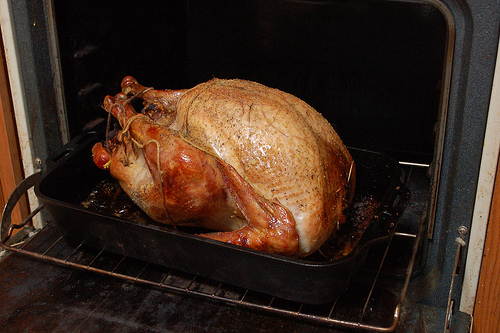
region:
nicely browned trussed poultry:
[79, 68, 364, 273]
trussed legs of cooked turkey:
[97, 67, 174, 137]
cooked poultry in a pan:
[33, 63, 422, 292]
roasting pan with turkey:
[28, 53, 418, 308]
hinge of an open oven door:
[4, 147, 60, 244]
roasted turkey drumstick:
[98, 86, 230, 217]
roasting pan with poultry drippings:
[326, 131, 413, 270]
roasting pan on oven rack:
[12, 48, 424, 329]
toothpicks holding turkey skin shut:
[320, 149, 368, 236]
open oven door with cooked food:
[5, 8, 489, 331]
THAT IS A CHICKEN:
[100, 72, 346, 249]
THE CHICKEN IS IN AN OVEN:
[101, 71, 356, 241]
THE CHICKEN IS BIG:
[95, 76, 351, 243]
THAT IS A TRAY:
[340, 191, 372, 257]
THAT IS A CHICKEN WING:
[211, 147, 295, 262]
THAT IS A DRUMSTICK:
[106, 90, 222, 200]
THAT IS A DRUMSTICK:
[126, 79, 183, 107]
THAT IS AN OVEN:
[13, 0, 481, 320]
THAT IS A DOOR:
[0, 127, 15, 174]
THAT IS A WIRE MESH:
[106, 257, 245, 288]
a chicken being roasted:
[106, 74, 366, 233]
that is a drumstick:
[140, 89, 192, 105]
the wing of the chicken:
[223, 162, 275, 249]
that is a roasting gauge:
[324, 262, 391, 327]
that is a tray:
[333, 223, 366, 253]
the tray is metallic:
[69, 177, 112, 216]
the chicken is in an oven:
[6, 12, 458, 286]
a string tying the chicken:
[115, 89, 140, 106]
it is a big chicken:
[98, 80, 362, 243]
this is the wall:
[307, 10, 371, 75]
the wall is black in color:
[314, 27, 353, 57]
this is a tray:
[102, 219, 124, 250]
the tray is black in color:
[150, 239, 193, 269]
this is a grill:
[20, 220, 43, 244]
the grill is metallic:
[25, 214, 47, 250]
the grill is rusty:
[16, 223, 46, 254]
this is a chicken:
[81, 59, 353, 242]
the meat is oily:
[178, 169, 273, 206]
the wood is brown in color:
[473, 289, 498, 319]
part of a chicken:
[269, 139, 321, 191]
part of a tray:
[215, 241, 246, 268]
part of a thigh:
[170, 175, 215, 237]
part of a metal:
[210, 287, 240, 311]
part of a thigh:
[267, 210, 303, 250]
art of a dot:
[267, 171, 299, 212]